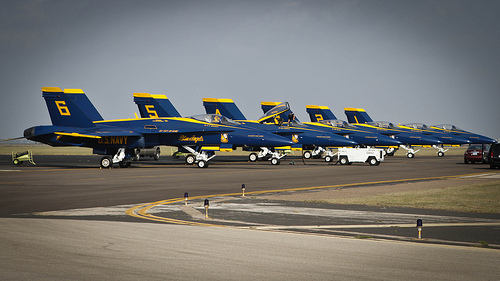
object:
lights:
[202, 198, 211, 219]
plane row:
[18, 80, 499, 166]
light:
[412, 216, 428, 240]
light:
[240, 183, 246, 196]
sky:
[0, 1, 498, 146]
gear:
[95, 152, 135, 169]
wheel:
[368, 157, 381, 166]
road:
[0, 151, 498, 280]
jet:
[201, 97, 402, 161]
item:
[10, 149, 36, 165]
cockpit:
[259, 102, 305, 127]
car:
[337, 144, 386, 166]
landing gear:
[101, 143, 138, 168]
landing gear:
[298, 147, 338, 160]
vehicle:
[463, 143, 491, 164]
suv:
[484, 139, 500, 170]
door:
[482, 143, 493, 164]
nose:
[271, 132, 296, 146]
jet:
[305, 104, 475, 158]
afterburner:
[22, 126, 41, 139]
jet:
[341, 106, 499, 159]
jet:
[257, 100, 445, 159]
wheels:
[338, 155, 353, 165]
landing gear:
[246, 142, 288, 166]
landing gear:
[429, 145, 451, 157]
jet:
[126, 93, 357, 162]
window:
[187, 113, 233, 125]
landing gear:
[401, 145, 420, 159]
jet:
[23, 86, 303, 169]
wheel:
[196, 160, 210, 169]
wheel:
[99, 156, 113, 168]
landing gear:
[181, 145, 214, 169]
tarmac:
[0, 160, 498, 280]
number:
[52, 100, 72, 116]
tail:
[19, 87, 102, 147]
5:
[144, 105, 160, 119]